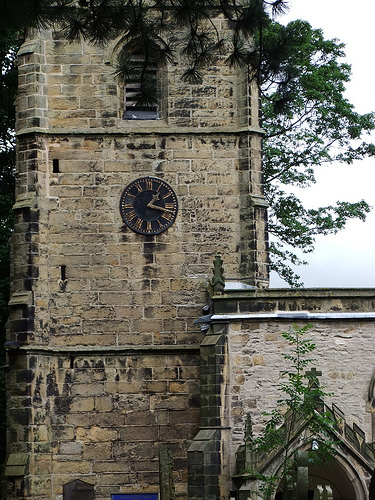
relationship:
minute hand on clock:
[169, 210, 175, 215] [115, 170, 181, 241]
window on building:
[121, 33, 163, 121] [3, 11, 269, 499]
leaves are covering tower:
[177, 30, 242, 85] [25, 32, 277, 410]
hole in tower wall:
[56, 264, 69, 286] [9, 41, 267, 382]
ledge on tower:
[23, 346, 200, 350] [7, 3, 264, 342]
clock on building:
[118, 178, 178, 237] [3, 11, 269, 499]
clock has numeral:
[114, 177, 178, 238] [145, 179, 154, 190]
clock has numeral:
[114, 177, 178, 238] [132, 182, 144, 198]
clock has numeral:
[114, 177, 178, 238] [125, 190, 136, 199]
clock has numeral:
[114, 177, 178, 238] [121, 208, 137, 222]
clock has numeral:
[114, 177, 178, 238] [142, 218, 156, 235]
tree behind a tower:
[129, 0, 298, 84] [0, 30, 263, 357]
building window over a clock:
[111, 25, 175, 129] [118, 178, 178, 237]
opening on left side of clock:
[52, 158, 58, 174] [116, 176, 181, 237]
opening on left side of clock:
[57, 260, 67, 283] [116, 176, 181, 237]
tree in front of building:
[286, 334, 306, 407] [203, 282, 370, 408]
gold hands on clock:
[146, 187, 177, 217] [112, 173, 182, 237]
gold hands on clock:
[146, 204, 174, 217] [116, 176, 181, 237]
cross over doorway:
[292, 358, 340, 399] [260, 407, 367, 498]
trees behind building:
[256, 6, 373, 288] [3, 11, 269, 499]